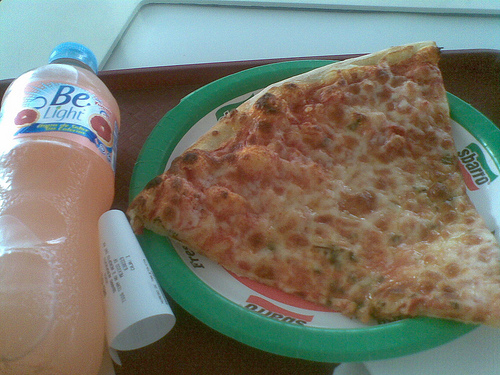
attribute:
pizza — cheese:
[128, 41, 500, 326]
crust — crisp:
[121, 41, 440, 233]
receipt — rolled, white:
[98, 207, 177, 366]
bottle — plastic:
[0, 41, 122, 375]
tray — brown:
[1, 48, 500, 375]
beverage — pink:
[1, 66, 122, 375]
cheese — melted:
[155, 56, 500, 325]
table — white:
[0, 0, 500, 80]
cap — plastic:
[49, 41, 97, 75]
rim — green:
[137, 230, 480, 373]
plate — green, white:
[127, 57, 494, 363]